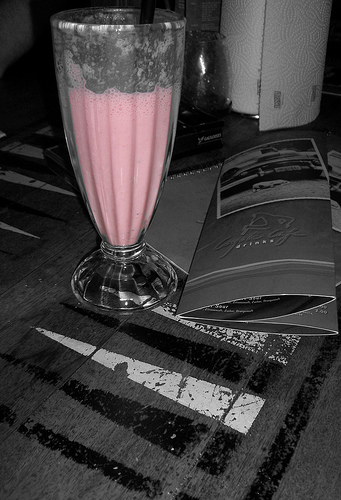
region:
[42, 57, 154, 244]
milkshake in the glass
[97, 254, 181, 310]
bottom of the glass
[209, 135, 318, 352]
menu on the table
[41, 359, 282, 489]
the table is wood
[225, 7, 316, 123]
purse on the table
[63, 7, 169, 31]
top of the glass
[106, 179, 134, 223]
the milkshake is pink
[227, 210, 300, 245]
name of the restaurant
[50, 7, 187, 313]
a tall glass of strawberry milkshake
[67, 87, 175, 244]
milkshake in a glass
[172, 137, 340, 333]
a menu in a cafe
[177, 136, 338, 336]
a menu in a restaurant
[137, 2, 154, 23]
the top of straw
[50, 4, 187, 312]
a strawberry milkshake served in a restaurant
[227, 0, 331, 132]
a roll of paper towels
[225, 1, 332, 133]
white paper towels on the table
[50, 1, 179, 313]
a glass of milkshake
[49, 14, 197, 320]
Glass with juice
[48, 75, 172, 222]
Pink color juice in side the glass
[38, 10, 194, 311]
A glass kept in the table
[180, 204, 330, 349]
Grey color invitation kept in the table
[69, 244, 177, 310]
Bottom of the glass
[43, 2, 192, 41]
Top of the glass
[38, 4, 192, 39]
Circle shape of the glass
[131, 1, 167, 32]
Black color straw kept in side the glass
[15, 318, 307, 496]
Black and white color line in the table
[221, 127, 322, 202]
Some photo kept near the glass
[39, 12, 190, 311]
this is a glasss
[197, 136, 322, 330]
this is a menu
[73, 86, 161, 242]
this is juice in a glass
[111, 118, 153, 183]
this is made of glass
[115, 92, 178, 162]
this is made of glass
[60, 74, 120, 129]
this is made of glass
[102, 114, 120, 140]
part of a glass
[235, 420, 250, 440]
rdge of a line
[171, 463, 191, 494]
art of a line